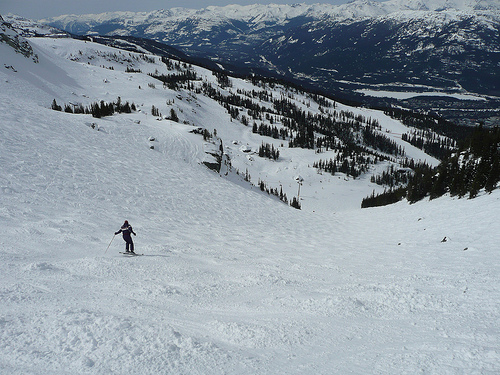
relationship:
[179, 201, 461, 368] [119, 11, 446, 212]
snow on hill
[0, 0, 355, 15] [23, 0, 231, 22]
clouds in sky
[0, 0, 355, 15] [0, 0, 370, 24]
clouds in sky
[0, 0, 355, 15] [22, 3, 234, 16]
clouds in sky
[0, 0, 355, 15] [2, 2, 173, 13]
clouds in sky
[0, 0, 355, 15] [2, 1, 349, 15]
clouds in sky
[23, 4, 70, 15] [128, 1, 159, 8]
clouds in sky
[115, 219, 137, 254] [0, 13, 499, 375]
skier in snow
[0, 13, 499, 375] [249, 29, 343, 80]
snow on hill side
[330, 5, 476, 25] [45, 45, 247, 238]
snow on hillside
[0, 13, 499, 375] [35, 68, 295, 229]
snow on hillside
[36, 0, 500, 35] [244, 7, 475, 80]
snow on hill side